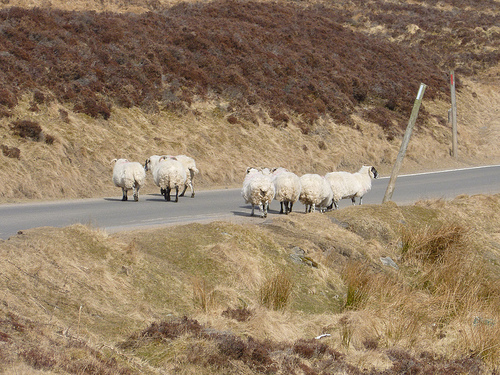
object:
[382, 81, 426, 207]
wood pole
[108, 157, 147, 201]
sheep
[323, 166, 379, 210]
sheep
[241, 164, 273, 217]
sheep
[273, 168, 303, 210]
sheep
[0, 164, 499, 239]
street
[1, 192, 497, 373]
grass area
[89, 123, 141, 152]
grass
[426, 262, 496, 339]
grass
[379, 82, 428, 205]
pole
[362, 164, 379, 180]
head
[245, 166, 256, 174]
head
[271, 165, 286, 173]
head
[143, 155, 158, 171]
head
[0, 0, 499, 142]
darkbrown grass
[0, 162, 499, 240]
road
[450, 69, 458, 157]
pole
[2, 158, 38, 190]
grass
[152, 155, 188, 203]
sheep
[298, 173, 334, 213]
sheep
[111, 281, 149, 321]
grass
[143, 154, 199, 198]
sheep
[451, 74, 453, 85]
paint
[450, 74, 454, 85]
sticker